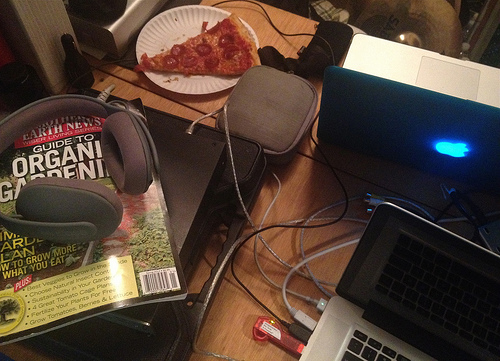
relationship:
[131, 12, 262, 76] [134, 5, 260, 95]
pizza on top of plate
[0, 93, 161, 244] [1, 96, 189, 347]
head phone on top of magazine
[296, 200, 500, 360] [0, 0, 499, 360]
laptop on top of desk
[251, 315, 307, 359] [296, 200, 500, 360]
flash drive connected to laptop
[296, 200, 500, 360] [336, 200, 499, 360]
laptop has monitor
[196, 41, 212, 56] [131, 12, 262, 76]
pepperoni on top of pizza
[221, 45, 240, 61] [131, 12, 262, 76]
pepperoni on top of pizza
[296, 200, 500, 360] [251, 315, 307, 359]
laptop with flash drive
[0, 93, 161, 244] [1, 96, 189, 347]
head phone above magazine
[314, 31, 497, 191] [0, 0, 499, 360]
laptop on top of desk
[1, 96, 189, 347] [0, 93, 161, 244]
magazine under head phone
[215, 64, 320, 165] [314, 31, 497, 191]
compact disc wallet next to laptop